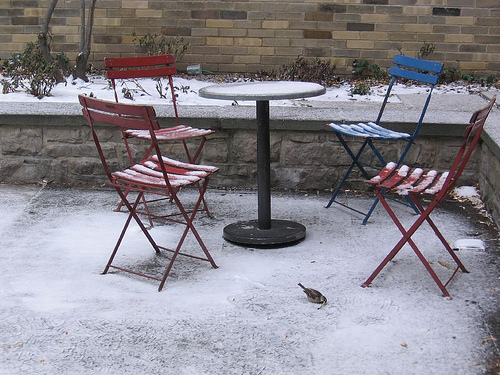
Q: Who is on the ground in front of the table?
A: Bird.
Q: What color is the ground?
A: White.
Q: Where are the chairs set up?
A: Around the table.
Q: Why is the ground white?
A: Snow.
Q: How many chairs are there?
A: Four.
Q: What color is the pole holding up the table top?
A: Black.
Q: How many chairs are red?
A: Three.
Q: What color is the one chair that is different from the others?
A: Blue.